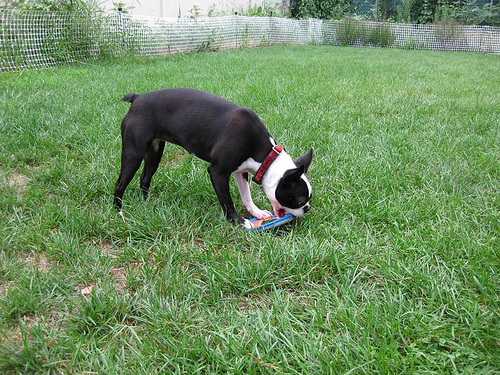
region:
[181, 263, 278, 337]
long green and yellow grass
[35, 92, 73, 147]
long green and yellow grass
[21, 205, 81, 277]
long green and yellow grass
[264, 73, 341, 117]
long green and yellow grass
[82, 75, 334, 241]
Dog playing with frisbee on grass.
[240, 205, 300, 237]
Blue frisbee in dog's mouth.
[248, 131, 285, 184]
Red collar around dog's neck.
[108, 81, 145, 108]
A dog's bob tail.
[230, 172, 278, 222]
Dog's white left front leg.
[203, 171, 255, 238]
Dog's black right front leg.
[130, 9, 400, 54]
Wire fence around yard.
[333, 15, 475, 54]
Weeds growing next to fence.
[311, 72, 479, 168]
Green grass growing in yard.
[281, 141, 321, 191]
Dog's two black erect ears.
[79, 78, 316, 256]
Dog is standing in grass.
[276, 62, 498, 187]
Grass is green color.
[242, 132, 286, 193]
Collar is red color.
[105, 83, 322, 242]
Dog is black and white color.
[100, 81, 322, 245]
Dog is playing with frisbee.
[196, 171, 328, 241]
Frisbee is blue color.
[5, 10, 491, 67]
Chain fence is white color.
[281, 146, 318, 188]
Two pointed ears for dog.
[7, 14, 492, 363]
Day time picture.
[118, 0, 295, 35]
Wall is white color.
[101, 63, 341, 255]
black and white dog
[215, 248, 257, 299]
long green and yellow grass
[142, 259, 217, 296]
long green and yellow grass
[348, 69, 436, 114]
long green and yellow grass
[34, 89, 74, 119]
long green and yellow grass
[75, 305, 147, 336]
long green and yellow grass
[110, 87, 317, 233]
Black and white dog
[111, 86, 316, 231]
Dog biting a frisbee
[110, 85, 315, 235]
Dog playing with a frisbee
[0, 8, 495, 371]
Fenced in backyard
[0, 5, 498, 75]
Net fencing surrounding a yard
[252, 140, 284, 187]
Red leather dog collar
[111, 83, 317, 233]
Dog playing in a yard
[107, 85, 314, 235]
Dog trying to hold a frisbee with his mouth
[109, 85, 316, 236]
Dog with a short stubby tail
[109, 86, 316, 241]
Dog with three black legs and one white leg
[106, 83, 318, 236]
dog playing with frisbee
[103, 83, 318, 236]
dog chewing on frisbee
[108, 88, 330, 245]
dog wearing a red collar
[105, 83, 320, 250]
dog playing in the grass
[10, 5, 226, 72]
fence surrounding a yard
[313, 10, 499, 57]
weeds growing around a fence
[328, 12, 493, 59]
fence surrounding a yard